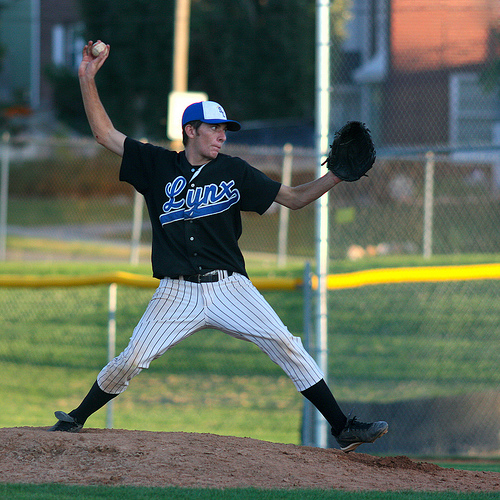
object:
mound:
[2, 427, 497, 491]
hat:
[181, 99, 242, 133]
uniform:
[76, 137, 343, 423]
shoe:
[336, 419, 389, 454]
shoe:
[48, 410, 83, 432]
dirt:
[122, 435, 265, 477]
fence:
[0, 145, 497, 256]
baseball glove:
[327, 121, 378, 182]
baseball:
[91, 42, 108, 57]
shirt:
[118, 136, 281, 278]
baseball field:
[0, 428, 498, 500]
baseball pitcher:
[54, 40, 386, 459]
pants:
[94, 273, 320, 402]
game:
[0, 0, 500, 500]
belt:
[168, 263, 232, 283]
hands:
[327, 120, 378, 183]